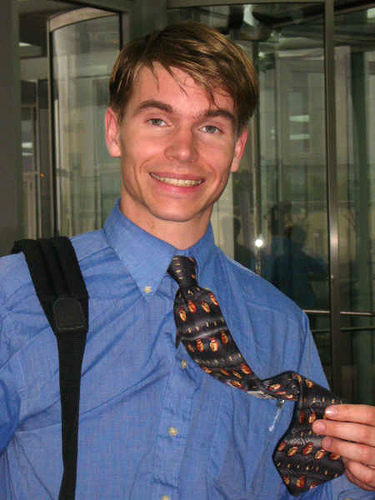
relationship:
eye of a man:
[142, 110, 171, 133] [0, 23, 375, 500]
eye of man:
[142, 110, 171, 133] [0, 23, 375, 500]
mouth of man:
[147, 166, 211, 200] [0, 23, 375, 500]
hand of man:
[316, 402, 373, 490] [0, 23, 375, 500]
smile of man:
[147, 166, 211, 200] [0, 23, 375, 500]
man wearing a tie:
[0, 23, 375, 500] [167, 255, 317, 496]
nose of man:
[170, 135, 203, 166] [0, 23, 375, 500]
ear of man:
[98, 103, 123, 165] [0, 23, 375, 500]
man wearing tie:
[0, 23, 375, 500] [167, 255, 317, 496]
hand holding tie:
[316, 402, 373, 490] [167, 255, 317, 496]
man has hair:
[0, 23, 375, 500] [98, 32, 259, 109]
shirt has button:
[2, 237, 365, 494] [143, 285, 152, 295]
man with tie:
[3, 15, 373, 496] [167, 255, 346, 495]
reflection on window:
[262, 224, 331, 333] [251, 14, 341, 412]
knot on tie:
[167, 255, 205, 287] [167, 255, 346, 495]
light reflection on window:
[251, 232, 263, 251] [217, 10, 332, 382]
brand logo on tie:
[251, 388, 272, 404] [167, 255, 346, 495]